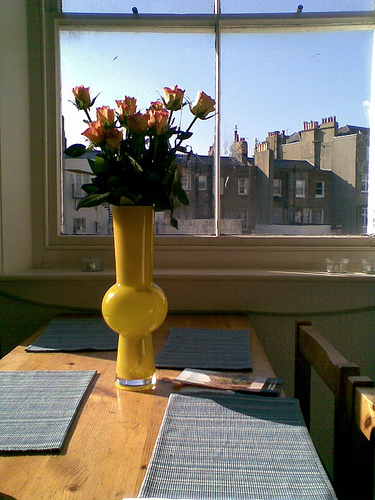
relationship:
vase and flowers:
[99, 201, 167, 399] [57, 82, 219, 207]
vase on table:
[99, 201, 167, 399] [83, 390, 146, 499]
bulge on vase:
[102, 281, 167, 337] [99, 201, 167, 399]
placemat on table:
[145, 394, 333, 499] [83, 390, 146, 499]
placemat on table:
[155, 321, 252, 377] [83, 390, 146, 499]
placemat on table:
[1, 367, 98, 455] [83, 390, 146, 499]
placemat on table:
[28, 318, 107, 355] [83, 390, 146, 499]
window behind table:
[34, 1, 374, 262] [83, 390, 146, 499]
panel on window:
[219, 27, 375, 245] [34, 1, 374, 262]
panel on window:
[56, 25, 214, 88] [34, 1, 374, 262]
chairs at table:
[292, 321, 375, 446] [83, 390, 146, 499]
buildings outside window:
[187, 117, 369, 235] [34, 1, 374, 262]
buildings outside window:
[58, 157, 109, 237] [34, 1, 374, 262]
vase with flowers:
[99, 201, 167, 399] [57, 82, 219, 207]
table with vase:
[83, 390, 146, 499] [99, 201, 167, 399]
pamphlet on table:
[172, 363, 284, 395] [83, 390, 146, 499]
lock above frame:
[131, 4, 304, 18] [50, 13, 374, 30]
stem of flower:
[83, 108, 95, 128] [72, 84, 94, 112]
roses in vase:
[57, 82, 219, 207] [99, 201, 167, 399]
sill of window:
[8, 273, 374, 287] [34, 1, 374, 262]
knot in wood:
[63, 484, 82, 495] [1, 458, 138, 499]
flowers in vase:
[57, 82, 219, 207] [99, 201, 167, 399]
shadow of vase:
[154, 377, 303, 438] [99, 201, 167, 399]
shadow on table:
[154, 377, 303, 438] [83, 390, 146, 499]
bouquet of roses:
[57, 82, 219, 207] [65, 85, 215, 151]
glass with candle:
[79, 254, 104, 272] [86, 259, 96, 273]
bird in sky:
[111, 54, 121, 64] [218, 34, 367, 115]